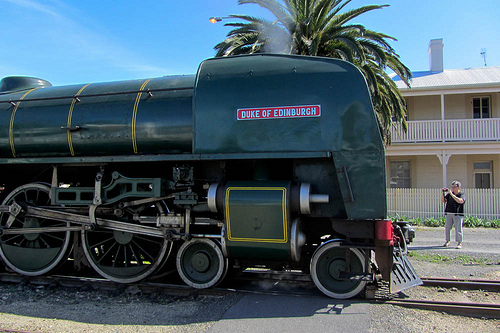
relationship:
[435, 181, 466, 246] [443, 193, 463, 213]
man with shirt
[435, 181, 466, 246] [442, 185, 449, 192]
man holding camera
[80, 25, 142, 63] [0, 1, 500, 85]
clouds in sky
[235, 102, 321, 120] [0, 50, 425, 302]
name of green train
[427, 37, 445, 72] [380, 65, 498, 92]
chimney on roof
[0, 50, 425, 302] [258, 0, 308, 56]
green train has train steam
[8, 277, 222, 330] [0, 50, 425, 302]
gravel next to green train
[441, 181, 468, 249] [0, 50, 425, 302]
man taking picture of green train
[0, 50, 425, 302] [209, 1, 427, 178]
green train next to tree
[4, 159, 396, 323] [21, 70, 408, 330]
wheels of train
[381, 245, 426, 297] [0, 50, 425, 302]
steam shovel on green train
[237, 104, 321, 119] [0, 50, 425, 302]
sign on green train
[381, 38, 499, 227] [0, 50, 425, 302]
beige house behind green train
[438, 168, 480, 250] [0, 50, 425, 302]
person standing behind green train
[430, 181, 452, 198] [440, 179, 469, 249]
camera of person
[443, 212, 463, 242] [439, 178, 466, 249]
khaki pants of person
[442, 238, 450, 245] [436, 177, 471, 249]
white shoe of person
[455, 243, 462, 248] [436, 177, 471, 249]
shoe of person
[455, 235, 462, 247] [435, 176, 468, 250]
shoe of person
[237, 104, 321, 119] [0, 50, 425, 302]
sign of green train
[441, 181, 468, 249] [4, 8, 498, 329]
man taking a picture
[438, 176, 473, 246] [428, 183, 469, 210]
woman taking a picture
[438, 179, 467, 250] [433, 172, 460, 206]
person taking a picture